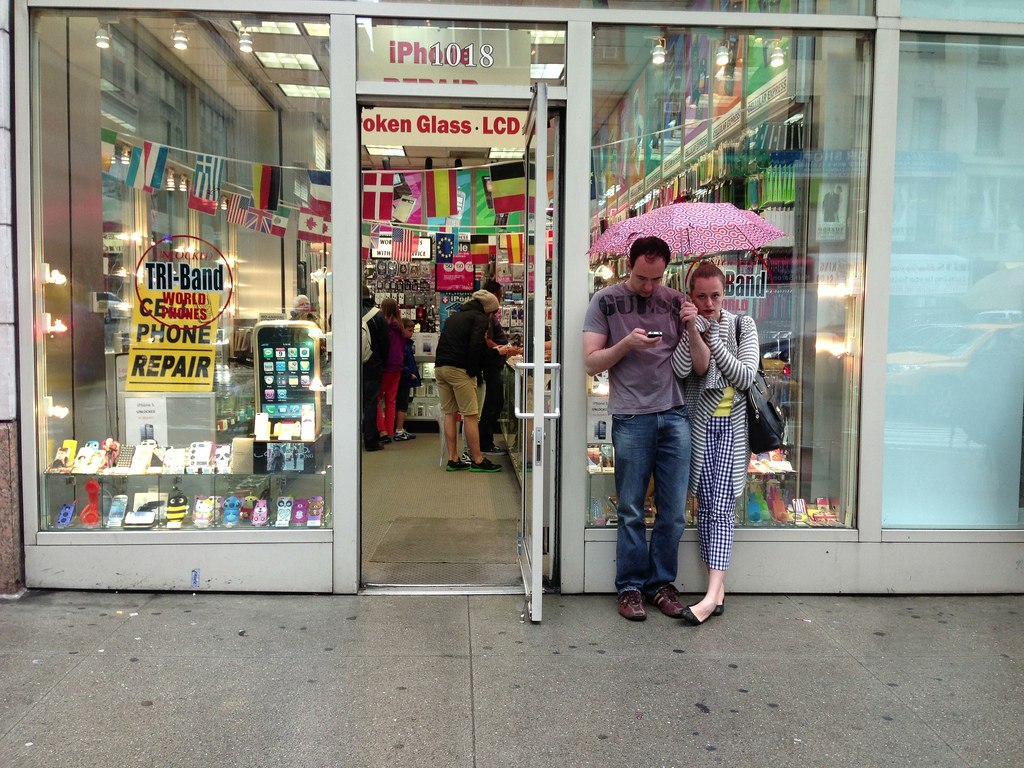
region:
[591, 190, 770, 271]
man holding a umbrella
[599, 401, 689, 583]
man wearing blue jeans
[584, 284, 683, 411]
man wearing a purple tee shirt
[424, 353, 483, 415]
man wearing brown shorts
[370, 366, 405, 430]
woman wearing pink pants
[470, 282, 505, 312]
man wearing a brown hat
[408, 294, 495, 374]
man wearing a black shirt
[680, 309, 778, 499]
woman wearing black and white jacket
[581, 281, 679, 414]
man wearing a purple shirt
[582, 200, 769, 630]
people sharing an umbrella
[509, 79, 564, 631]
store door open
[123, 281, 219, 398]
cell phone repair sign in window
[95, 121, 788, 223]
world flags hanging across store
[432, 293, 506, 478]
man wearing tan shorts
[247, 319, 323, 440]
giant iphone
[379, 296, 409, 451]
girl wearing red pants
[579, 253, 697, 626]
a man looking at a phone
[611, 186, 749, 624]
a man holding a pink umbrella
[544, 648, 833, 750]
chewing gum stuck to the sidewalk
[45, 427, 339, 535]
items on display in a store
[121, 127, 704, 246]
flags hanging from ropes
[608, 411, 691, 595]
a person wearing blue jeans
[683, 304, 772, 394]
a person wearing a striped shirt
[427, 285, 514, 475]
person bending over a display case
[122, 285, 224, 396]
advertisement sign for cell phone repair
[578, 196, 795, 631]
couple standing under an umbrella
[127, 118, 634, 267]
hanging display of international flags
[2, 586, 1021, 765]
sidewalk spotted with stains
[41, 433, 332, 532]
display case containing a variety of phones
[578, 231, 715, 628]
man looking at his cell phone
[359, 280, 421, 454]
people standing inside a shop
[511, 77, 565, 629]
glass door standing open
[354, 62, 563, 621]
store door is open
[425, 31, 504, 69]
1018 written above the door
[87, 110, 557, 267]
banners of flags in the store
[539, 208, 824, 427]
two people outside the store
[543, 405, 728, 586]
pants on the man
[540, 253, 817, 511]
woman holding onto man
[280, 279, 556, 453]
people in the store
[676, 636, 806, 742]
marks on the ground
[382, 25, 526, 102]
number above the entrance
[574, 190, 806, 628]
Couple huddling close under a single umbrella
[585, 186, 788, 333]
Pink polka dotted umbrella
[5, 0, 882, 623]
Phone repair shop open with several customers inside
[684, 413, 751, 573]
Blue with white striped plaid pants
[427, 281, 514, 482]
Old man looking down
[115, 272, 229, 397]
Yellow phone repair sign with black text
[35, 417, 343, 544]
Phones displayed in a glass container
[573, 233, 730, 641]
Middle aged man looking at his phone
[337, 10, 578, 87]
Sign displaying street address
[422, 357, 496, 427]
Khaki shorts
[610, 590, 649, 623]
a man's brown shoe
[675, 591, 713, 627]
a woman's black shoe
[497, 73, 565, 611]
an open door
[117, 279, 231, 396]
a large black and yellow sign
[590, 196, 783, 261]
a large pink umbrella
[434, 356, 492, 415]
a man's brown shorts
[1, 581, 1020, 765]
a concrete sidewalk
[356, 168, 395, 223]
a red and white flag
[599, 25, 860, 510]
a large store window